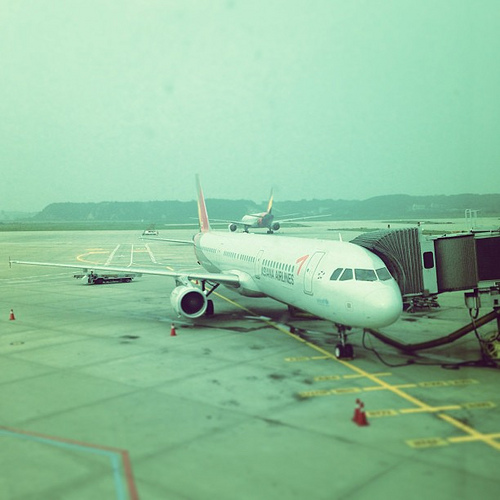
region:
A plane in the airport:
[173, 206, 401, 335]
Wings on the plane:
[42, 257, 174, 282]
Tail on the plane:
[187, 173, 212, 231]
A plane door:
[298, 243, 325, 295]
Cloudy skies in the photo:
[156, 71, 269, 156]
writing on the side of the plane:
[258, 263, 296, 283]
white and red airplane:
[14, 174, 404, 358]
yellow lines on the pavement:
[76, 238, 498, 450]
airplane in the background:
[193, 189, 330, 237]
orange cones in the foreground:
[352, 395, 369, 427]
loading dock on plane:
[346, 226, 498, 309]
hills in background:
[25, 192, 497, 225]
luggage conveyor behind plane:
[72, 267, 140, 283]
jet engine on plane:
[172, 285, 204, 315]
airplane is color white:
[3, 159, 488, 437]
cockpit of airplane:
[307, 241, 407, 333]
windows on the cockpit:
[323, 257, 394, 287]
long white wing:
[8, 249, 262, 287]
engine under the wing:
[156, 259, 228, 325]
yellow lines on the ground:
[334, 341, 492, 456]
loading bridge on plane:
[328, 211, 496, 319]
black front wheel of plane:
[326, 330, 361, 368]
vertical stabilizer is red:
[186, 166, 218, 236]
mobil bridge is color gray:
[356, 209, 498, 309]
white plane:
[123, 190, 393, 368]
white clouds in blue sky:
[235, 55, 310, 106]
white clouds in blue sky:
[418, 23, 476, 84]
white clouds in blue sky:
[390, 113, 438, 147]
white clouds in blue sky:
[24, 69, 95, 121]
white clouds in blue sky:
[228, 65, 303, 115]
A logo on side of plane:
[259, 265, 295, 283]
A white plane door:
[303, 250, 325, 291]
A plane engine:
[168, 283, 207, 320]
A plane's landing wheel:
[333, 342, 355, 359]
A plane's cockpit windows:
[330, 263, 391, 285]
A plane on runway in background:
[213, 188, 282, 235]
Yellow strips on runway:
[76, 239, 498, 453]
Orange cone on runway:
[8, 308, 16, 321]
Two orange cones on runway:
[350, 397, 369, 426]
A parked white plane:
[12, 175, 403, 357]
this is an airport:
[24, 73, 389, 420]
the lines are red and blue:
[30, 411, 167, 485]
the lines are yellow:
[315, 323, 480, 438]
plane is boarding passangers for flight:
[128, 177, 454, 352]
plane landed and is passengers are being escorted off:
[180, 233, 459, 368]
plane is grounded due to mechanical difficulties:
[97, 238, 487, 356]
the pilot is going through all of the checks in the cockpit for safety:
[127, 179, 450, 391]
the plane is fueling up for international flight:
[55, 228, 476, 362]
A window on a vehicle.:
[338, 265, 354, 288]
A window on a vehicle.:
[351, 267, 373, 284]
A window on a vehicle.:
[330, 265, 340, 290]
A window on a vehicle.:
[290, 262, 296, 274]